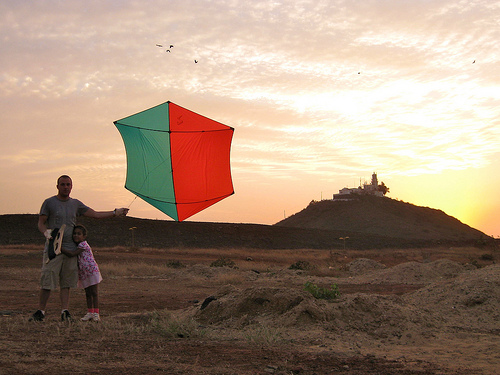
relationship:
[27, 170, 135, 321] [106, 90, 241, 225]
man holding kite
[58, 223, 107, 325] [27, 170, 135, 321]
girl beside man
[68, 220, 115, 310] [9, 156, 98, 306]
girl hugging guy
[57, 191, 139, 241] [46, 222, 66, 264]
string has hold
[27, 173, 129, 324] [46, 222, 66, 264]
guy holding hold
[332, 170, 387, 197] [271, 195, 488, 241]
building on top of hill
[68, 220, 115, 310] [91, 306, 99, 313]
girl wearing sock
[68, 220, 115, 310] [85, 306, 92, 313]
girl wearing sock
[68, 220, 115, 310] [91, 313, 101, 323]
girl wearing shoe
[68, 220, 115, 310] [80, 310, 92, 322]
girl wearing shoe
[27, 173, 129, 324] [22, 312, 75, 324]
guy wearing shoes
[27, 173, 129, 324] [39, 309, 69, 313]
guy wearing socks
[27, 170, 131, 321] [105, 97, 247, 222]
man flying kite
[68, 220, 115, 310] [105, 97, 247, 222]
girl flying kite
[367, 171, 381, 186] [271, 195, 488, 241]
lighthouse on hill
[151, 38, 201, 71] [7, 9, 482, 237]
birds flying in sky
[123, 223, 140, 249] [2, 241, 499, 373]
pole in ground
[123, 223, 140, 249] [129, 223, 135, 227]
pole has lights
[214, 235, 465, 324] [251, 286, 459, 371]
weeds growing in dirt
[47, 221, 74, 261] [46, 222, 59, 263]
spool has string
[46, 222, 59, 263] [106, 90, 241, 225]
string for kite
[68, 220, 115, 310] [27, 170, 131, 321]
girl hugging man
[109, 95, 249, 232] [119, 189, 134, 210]
kite has string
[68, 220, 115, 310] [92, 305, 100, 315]
girl has sock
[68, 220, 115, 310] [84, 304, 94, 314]
girl has sock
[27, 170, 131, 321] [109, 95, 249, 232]
man with kite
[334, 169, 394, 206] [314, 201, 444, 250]
house on hill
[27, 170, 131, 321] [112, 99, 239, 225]
man holding kite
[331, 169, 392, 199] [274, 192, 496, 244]
house on a hill